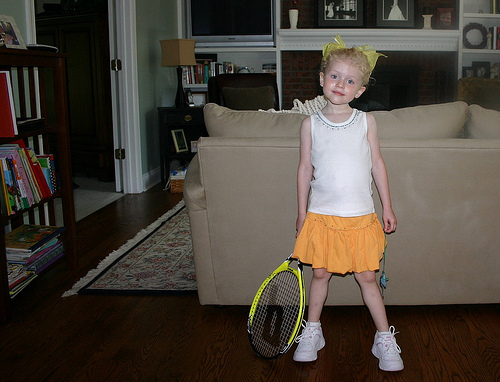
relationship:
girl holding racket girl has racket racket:
[247, 43, 412, 374] [241, 232, 318, 362]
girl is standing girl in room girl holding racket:
[247, 43, 412, 374] [247, 43, 412, 374]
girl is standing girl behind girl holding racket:
[247, 43, 412, 374] [247, 43, 412, 374]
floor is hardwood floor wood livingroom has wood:
[48, 299, 209, 369] [7, 5, 496, 378]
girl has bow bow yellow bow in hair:
[314, 38, 385, 115] [324, 36, 383, 71]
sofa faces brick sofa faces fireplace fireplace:
[207, 45, 495, 186] [280, 51, 455, 112]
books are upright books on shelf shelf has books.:
[3, 140, 60, 216] [3, 43, 69, 209]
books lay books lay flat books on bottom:
[9, 232, 66, 296] [2, 198, 86, 303]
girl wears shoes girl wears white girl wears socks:
[295, 319, 404, 376] [295, 311, 409, 374]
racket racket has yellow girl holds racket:
[241, 232, 318, 362] [247, 43, 412, 374]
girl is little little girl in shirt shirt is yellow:
[247, 43, 412, 374] [309, 106, 379, 219]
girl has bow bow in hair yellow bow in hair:
[314, 38, 385, 115] [324, 36, 383, 71]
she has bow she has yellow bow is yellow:
[314, 38, 385, 115] [324, 36, 383, 71]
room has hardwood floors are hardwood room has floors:
[4, 178, 243, 355] [111, 170, 496, 381]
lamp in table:
[162, 36, 195, 117] [148, 93, 200, 191]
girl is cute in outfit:
[247, 43, 412, 374] [291, 110, 393, 275]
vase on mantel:
[284, 8, 304, 28] [166, 1, 484, 101]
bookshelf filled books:
[0, 2, 89, 296] [5, 61, 41, 136]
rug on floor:
[63, 199, 201, 299] [65, 187, 194, 310]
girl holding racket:
[251, 30, 414, 380] [243, 250, 306, 362]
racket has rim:
[241, 232, 318, 373] [291, 281, 310, 347]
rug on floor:
[63, 199, 201, 299] [15, 296, 228, 380]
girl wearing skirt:
[251, 30, 414, 380] [293, 206, 389, 269]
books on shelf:
[1, 68, 63, 297] [0, 48, 77, 329]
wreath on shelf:
[460, 20, 489, 49] [460, 43, 498, 54]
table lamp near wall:
[157, 38, 198, 107] [127, 0, 183, 193]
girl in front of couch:
[251, 30, 414, 380] [183, 101, 498, 305]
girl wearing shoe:
[251, 30, 414, 380] [370, 325, 407, 374]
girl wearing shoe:
[251, 30, 414, 380] [292, 315, 326, 364]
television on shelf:
[185, 1, 273, 45] [189, 42, 279, 53]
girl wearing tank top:
[251, 30, 414, 380] [303, 105, 375, 220]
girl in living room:
[251, 30, 414, 380] [2, 1, 498, 379]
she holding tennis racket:
[290, 39, 406, 375] [249, 249, 304, 361]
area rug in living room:
[61, 196, 198, 299] [2, 1, 498, 379]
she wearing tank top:
[290, 39, 406, 375] [303, 105, 375, 220]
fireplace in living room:
[280, 51, 455, 112] [2, 1, 498, 379]